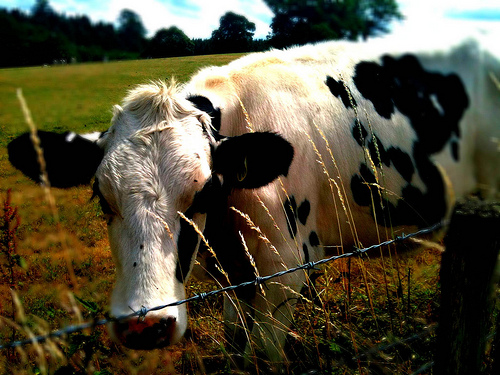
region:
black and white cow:
[7, 18, 497, 371]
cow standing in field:
[0, 50, 492, 370]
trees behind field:
[0, 0, 402, 70]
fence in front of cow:
[0, 181, 495, 371]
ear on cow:
[7, 128, 103, 189]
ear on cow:
[210, 130, 293, 195]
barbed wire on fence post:
[0, 208, 449, 372]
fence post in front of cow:
[432, 195, 498, 373]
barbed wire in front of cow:
[3, 219, 444, 371]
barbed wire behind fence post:
[432, 195, 496, 372]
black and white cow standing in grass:
[7, 29, 499, 374]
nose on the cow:
[114, 308, 176, 352]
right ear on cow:
[6, 128, 102, 190]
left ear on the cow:
[210, 131, 294, 191]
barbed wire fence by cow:
[2, 215, 498, 353]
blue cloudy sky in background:
[0, 0, 497, 39]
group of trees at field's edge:
[0, 0, 407, 67]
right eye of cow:
[87, 175, 118, 220]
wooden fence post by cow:
[433, 200, 496, 373]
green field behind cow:
[2, 50, 296, 182]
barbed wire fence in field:
[11, 245, 406, 332]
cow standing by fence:
[1, 83, 499, 354]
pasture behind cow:
[20, 59, 164, 82]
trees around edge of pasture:
[23, 13, 240, 55]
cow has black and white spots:
[258, 65, 498, 220]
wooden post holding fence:
[441, 196, 498, 373]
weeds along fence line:
[166, 212, 428, 357]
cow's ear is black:
[207, 135, 299, 185]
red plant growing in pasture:
[0, 181, 38, 292]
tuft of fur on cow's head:
[121, 78, 197, 142]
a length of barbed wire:
[188, 214, 498, 288]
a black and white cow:
[15, 65, 492, 360]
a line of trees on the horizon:
[12, 10, 359, 71]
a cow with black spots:
[14, 16, 498, 351]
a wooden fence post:
[425, 179, 499, 374]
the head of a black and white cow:
[15, 96, 292, 355]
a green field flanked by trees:
[5, 4, 183, 81]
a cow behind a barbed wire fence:
[13, 55, 495, 356]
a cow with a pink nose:
[23, 79, 292, 364]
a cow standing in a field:
[20, 59, 498, 373]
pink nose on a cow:
[116, 312, 187, 348]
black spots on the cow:
[319, 54, 471, 179]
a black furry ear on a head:
[214, 117, 294, 194]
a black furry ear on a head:
[10, 112, 99, 184]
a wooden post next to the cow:
[447, 192, 494, 372]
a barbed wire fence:
[366, 233, 423, 248]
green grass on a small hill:
[36, 64, 120, 109]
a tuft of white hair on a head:
[130, 81, 192, 121]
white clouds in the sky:
[151, 0, 213, 26]